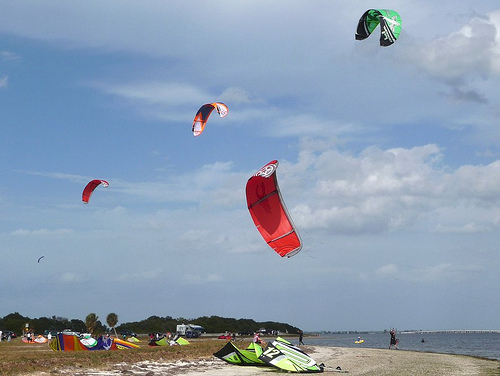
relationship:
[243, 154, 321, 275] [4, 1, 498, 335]
parasail in sky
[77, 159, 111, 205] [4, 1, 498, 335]
parasail in sky